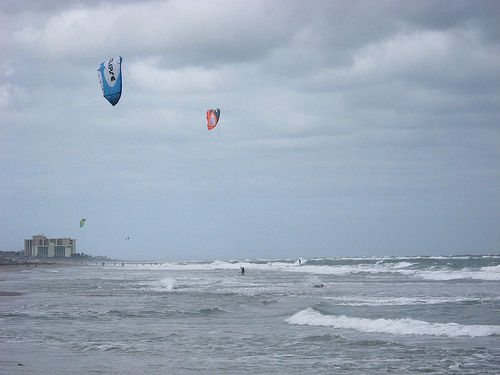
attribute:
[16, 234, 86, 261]
building — tan, brown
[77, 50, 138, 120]
kite — blue, white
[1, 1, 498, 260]
sky — cloudy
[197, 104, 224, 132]
kite — orange, triangular, red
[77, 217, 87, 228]
kite — green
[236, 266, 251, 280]
person — surfing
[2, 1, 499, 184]
clouds — grey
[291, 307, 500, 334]
waves — white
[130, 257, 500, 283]
waves — white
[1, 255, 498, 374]
water — clean